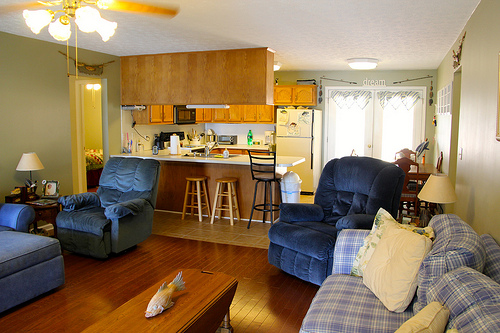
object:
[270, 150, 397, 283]
chair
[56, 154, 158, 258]
chair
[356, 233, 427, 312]
pillow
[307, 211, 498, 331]
couch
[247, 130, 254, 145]
bottle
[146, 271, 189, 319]
fish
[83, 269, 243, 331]
table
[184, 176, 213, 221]
stools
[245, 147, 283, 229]
stool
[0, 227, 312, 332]
floors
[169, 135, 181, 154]
towels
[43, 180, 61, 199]
frame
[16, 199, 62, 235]
table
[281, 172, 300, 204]
can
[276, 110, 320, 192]
refrigerator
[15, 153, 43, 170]
shade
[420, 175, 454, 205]
shade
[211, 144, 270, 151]
counter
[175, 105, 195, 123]
microwave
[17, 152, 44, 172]
lamp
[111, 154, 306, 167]
bar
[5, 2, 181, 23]
fan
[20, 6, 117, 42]
fixture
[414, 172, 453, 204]
lamp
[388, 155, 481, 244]
corner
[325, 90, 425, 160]
doors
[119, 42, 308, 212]
kitchen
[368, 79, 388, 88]
word